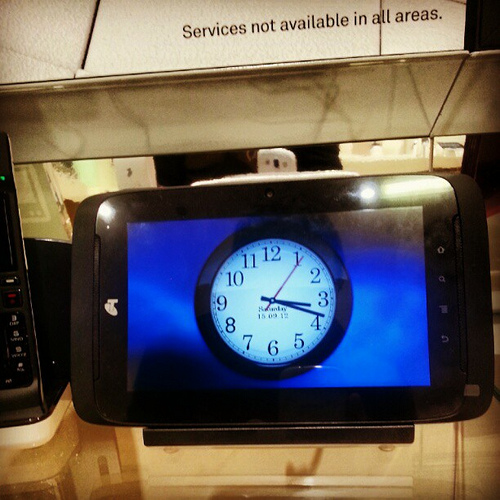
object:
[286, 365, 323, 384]
edge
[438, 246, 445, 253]
button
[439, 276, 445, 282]
button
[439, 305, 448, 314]
button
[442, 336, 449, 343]
button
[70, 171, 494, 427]
black phone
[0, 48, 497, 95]
ceiling edge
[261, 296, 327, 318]
han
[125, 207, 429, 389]
screen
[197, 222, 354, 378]
clock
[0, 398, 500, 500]
table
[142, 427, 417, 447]
handle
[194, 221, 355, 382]
frame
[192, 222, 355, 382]
clock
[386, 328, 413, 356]
part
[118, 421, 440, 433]
edge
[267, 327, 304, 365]
part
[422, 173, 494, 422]
side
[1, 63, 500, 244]
tabletop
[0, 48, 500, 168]
ceiling